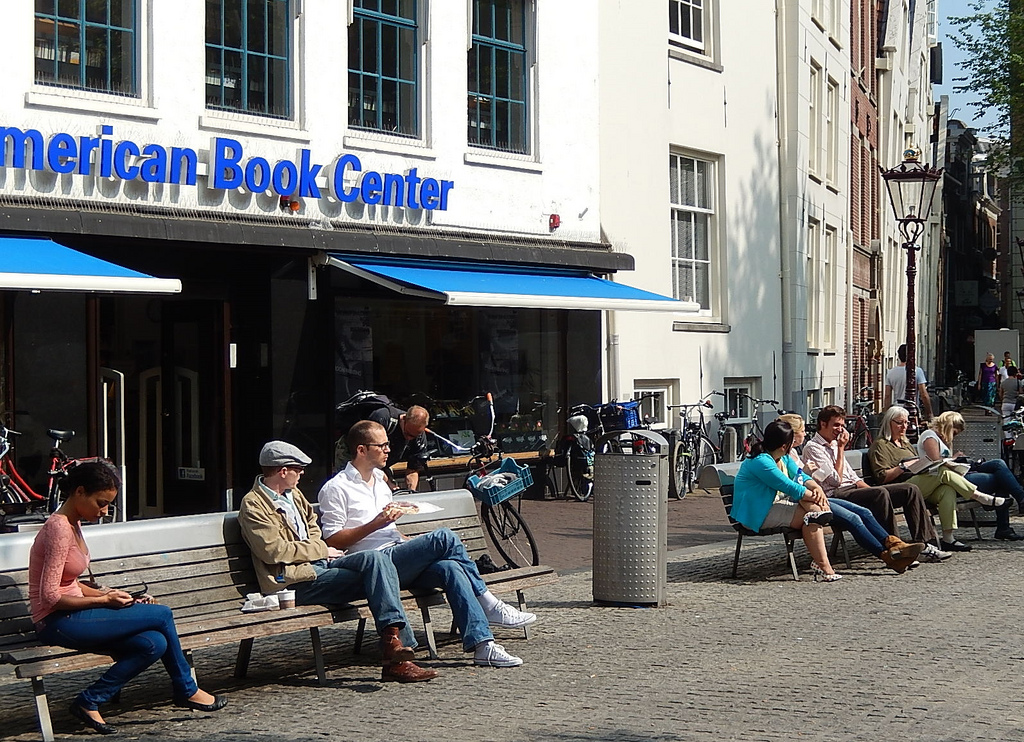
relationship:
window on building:
[670, 144, 722, 323] [606, 3, 950, 461]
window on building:
[673, 143, 726, 327] [606, 3, 950, 461]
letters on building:
[75, 133, 97, 172] [4, 5, 623, 610]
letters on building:
[94, 119, 120, 178] [4, 5, 623, 610]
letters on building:
[110, 135, 136, 177] [4, 5, 623, 610]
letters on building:
[136, 145, 158, 174] [4, 5, 623, 610]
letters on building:
[172, 141, 203, 180] [4, 5, 623, 610]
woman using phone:
[21, 448, 233, 738] [116, 580, 160, 615]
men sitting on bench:
[228, 424, 440, 682] [2, 482, 554, 738]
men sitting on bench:
[317, 413, 551, 675] [2, 482, 554, 738]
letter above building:
[209, 130, 244, 197] [4, 5, 623, 610]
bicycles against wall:
[401, 374, 549, 576] [315, 268, 629, 510]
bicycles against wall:
[527, 398, 601, 507] [315, 268, 629, 510]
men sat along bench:
[236, 439, 441, 682] [4, 448, 551, 738]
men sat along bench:
[318, 420, 537, 669] [4, 448, 551, 738]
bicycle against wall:
[4, 424, 126, 546] [8, 225, 186, 560]